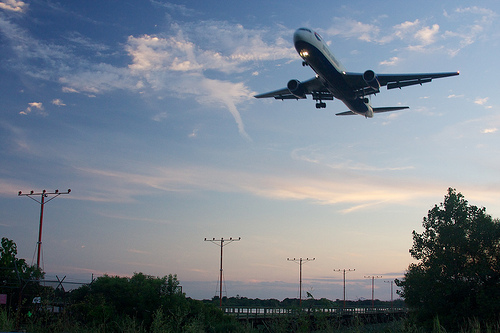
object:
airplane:
[250, 26, 460, 120]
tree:
[394, 185, 500, 319]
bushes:
[58, 270, 212, 333]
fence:
[0, 260, 98, 322]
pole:
[15, 188, 71, 272]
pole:
[202, 236, 240, 308]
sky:
[0, 0, 499, 301]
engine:
[285, 77, 308, 100]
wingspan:
[252, 64, 462, 107]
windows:
[323, 44, 331, 56]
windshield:
[295, 28, 314, 34]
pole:
[285, 256, 316, 308]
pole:
[333, 267, 356, 307]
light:
[299, 48, 311, 58]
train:
[0, 293, 42, 306]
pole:
[361, 274, 383, 310]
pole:
[382, 279, 398, 307]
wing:
[347, 70, 461, 90]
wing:
[252, 76, 330, 101]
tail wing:
[373, 106, 410, 114]